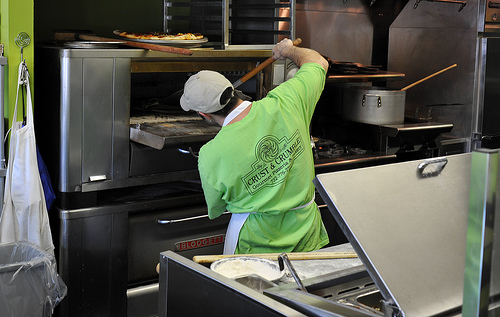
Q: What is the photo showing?
A: It is showing a kitchen.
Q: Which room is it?
A: It is a kitchen.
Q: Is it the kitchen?
A: Yes, it is the kitchen.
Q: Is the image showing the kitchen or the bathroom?
A: It is showing the kitchen.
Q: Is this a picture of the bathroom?
A: No, the picture is showing the kitchen.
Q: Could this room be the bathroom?
A: No, it is the kitchen.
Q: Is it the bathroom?
A: No, it is the kitchen.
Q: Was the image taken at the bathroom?
A: No, the picture was taken in the kitchen.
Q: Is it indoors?
A: Yes, it is indoors.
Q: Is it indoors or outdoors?
A: It is indoors.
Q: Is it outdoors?
A: No, it is indoors.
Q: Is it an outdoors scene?
A: No, it is indoors.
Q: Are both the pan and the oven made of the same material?
A: Yes, both the pan and the oven are made of metal.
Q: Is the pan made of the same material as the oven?
A: Yes, both the pan and the oven are made of metal.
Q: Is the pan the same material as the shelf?
A: Yes, both the pan and the shelf are made of metal.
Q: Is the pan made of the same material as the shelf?
A: Yes, both the pan and the shelf are made of metal.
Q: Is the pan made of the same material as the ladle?
A: Yes, both the pan and the ladle are made of metal.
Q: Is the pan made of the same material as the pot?
A: Yes, both the pan and the pot are made of metal.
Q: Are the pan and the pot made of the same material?
A: Yes, both the pan and the pot are made of metal.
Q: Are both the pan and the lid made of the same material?
A: Yes, both the pan and the lid are made of metal.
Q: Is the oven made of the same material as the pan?
A: Yes, both the oven and the pan are made of metal.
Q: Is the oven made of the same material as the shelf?
A: Yes, both the oven and the shelf are made of metal.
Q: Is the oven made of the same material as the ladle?
A: Yes, both the oven and the ladle are made of metal.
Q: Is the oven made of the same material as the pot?
A: Yes, both the oven and the pot are made of metal.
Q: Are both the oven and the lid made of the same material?
A: Yes, both the oven and the lid are made of metal.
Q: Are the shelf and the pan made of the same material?
A: Yes, both the shelf and the pan are made of metal.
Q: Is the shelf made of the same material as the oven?
A: Yes, both the shelf and the oven are made of metal.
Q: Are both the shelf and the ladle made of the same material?
A: Yes, both the shelf and the ladle are made of metal.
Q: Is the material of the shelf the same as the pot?
A: Yes, both the shelf and the pot are made of metal.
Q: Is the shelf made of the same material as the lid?
A: Yes, both the shelf and the lid are made of metal.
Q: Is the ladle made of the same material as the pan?
A: Yes, both the ladle and the pan are made of metal.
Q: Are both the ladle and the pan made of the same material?
A: Yes, both the ladle and the pan are made of metal.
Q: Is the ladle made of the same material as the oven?
A: Yes, both the ladle and the oven are made of metal.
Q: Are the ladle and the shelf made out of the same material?
A: Yes, both the ladle and the shelf are made of metal.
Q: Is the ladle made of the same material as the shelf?
A: Yes, both the ladle and the shelf are made of metal.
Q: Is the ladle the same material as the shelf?
A: Yes, both the ladle and the shelf are made of metal.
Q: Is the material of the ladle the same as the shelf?
A: Yes, both the ladle and the shelf are made of metal.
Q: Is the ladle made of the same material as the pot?
A: Yes, both the ladle and the pot are made of metal.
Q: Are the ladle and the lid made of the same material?
A: Yes, both the ladle and the lid are made of metal.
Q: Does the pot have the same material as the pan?
A: Yes, both the pot and the pan are made of metal.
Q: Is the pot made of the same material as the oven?
A: Yes, both the pot and the oven are made of metal.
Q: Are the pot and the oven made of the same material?
A: Yes, both the pot and the oven are made of metal.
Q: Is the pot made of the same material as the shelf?
A: Yes, both the pot and the shelf are made of metal.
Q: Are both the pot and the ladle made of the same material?
A: Yes, both the pot and the ladle are made of metal.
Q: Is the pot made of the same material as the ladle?
A: Yes, both the pot and the ladle are made of metal.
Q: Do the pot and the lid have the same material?
A: Yes, both the pot and the lid are made of metal.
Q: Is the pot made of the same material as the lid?
A: Yes, both the pot and the lid are made of metal.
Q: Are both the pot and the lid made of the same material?
A: Yes, both the pot and the lid are made of metal.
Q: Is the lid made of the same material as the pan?
A: Yes, both the lid and the pan are made of metal.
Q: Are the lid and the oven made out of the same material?
A: Yes, both the lid and the oven are made of metal.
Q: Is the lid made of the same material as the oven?
A: Yes, both the lid and the oven are made of metal.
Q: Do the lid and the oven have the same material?
A: Yes, both the lid and the oven are made of metal.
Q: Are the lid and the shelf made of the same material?
A: Yes, both the lid and the shelf are made of metal.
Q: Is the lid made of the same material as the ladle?
A: Yes, both the lid and the ladle are made of metal.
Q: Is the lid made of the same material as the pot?
A: Yes, both the lid and the pot are made of metal.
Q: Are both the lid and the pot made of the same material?
A: Yes, both the lid and the pot are made of metal.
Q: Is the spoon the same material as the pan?
A: No, the spoon is made of wood and the pan is made of metal.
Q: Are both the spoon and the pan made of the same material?
A: No, the spoon is made of wood and the pan is made of metal.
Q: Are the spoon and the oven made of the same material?
A: No, the spoon is made of wood and the oven is made of metal.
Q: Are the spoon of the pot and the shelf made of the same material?
A: No, the spoon is made of wood and the shelf is made of metal.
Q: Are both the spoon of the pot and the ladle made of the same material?
A: No, the spoon is made of wood and the ladle is made of metal.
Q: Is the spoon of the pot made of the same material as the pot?
A: No, the spoon is made of wood and the pot is made of metal.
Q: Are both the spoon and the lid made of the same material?
A: No, the spoon is made of wood and the lid is made of metal.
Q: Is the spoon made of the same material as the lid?
A: No, the spoon is made of wood and the lid is made of metal.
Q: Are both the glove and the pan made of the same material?
A: No, the glove is made of plastic and the pan is made of metal.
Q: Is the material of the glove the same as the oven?
A: No, the glove is made of plastic and the oven is made of metal.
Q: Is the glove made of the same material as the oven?
A: No, the glove is made of plastic and the oven is made of metal.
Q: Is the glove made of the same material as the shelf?
A: No, the glove is made of plastic and the shelf is made of metal.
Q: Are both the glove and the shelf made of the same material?
A: No, the glove is made of plastic and the shelf is made of metal.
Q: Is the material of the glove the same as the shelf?
A: No, the glove is made of plastic and the shelf is made of metal.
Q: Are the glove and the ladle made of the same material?
A: No, the glove is made of plastic and the ladle is made of metal.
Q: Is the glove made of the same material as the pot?
A: No, the glove is made of plastic and the pot is made of metal.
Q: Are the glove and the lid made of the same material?
A: No, the glove is made of plastic and the lid is made of metal.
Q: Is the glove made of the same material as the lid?
A: No, the glove is made of plastic and the lid is made of metal.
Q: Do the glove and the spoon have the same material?
A: No, the glove is made of plastic and the spoon is made of wood.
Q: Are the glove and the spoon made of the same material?
A: No, the glove is made of plastic and the spoon is made of wood.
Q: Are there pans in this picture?
A: Yes, there is a pan.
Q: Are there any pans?
A: Yes, there is a pan.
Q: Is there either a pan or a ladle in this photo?
A: Yes, there is a pan.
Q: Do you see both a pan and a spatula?
A: No, there is a pan but no spatulas.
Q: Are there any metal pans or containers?
A: Yes, there is a metal pan.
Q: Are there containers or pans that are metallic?
A: Yes, the pan is metallic.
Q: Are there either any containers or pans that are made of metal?
A: Yes, the pan is made of metal.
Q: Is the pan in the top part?
A: Yes, the pan is in the top of the image.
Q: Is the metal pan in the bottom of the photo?
A: No, the pan is in the top of the image.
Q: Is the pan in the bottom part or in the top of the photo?
A: The pan is in the top of the image.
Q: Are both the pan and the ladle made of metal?
A: Yes, both the pan and the ladle are made of metal.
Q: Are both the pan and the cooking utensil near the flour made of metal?
A: Yes, both the pan and the ladle are made of metal.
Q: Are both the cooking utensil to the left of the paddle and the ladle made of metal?
A: Yes, both the pan and the ladle are made of metal.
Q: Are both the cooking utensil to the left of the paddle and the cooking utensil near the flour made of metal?
A: Yes, both the pan and the ladle are made of metal.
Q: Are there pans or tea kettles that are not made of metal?
A: No, there is a pan but it is made of metal.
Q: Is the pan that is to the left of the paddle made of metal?
A: Yes, the pan is made of metal.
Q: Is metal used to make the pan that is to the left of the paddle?
A: Yes, the pan is made of metal.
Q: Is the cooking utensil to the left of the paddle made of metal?
A: Yes, the pan is made of metal.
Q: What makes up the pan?
A: The pan is made of metal.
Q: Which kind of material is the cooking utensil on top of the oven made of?
A: The pan is made of metal.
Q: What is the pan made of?
A: The pan is made of metal.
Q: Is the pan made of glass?
A: No, the pan is made of metal.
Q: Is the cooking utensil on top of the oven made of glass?
A: No, the pan is made of metal.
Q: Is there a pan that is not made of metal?
A: No, there is a pan but it is made of metal.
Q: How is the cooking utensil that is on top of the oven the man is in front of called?
A: The cooking utensil is a pan.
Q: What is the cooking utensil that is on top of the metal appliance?
A: The cooking utensil is a pan.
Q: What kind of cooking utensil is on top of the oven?
A: The cooking utensil is a pan.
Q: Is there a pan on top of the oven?
A: Yes, there is a pan on top of the oven.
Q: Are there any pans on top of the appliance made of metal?
A: Yes, there is a pan on top of the oven.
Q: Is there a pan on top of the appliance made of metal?
A: Yes, there is a pan on top of the oven.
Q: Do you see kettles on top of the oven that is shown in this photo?
A: No, there is a pan on top of the oven.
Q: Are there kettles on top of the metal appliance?
A: No, there is a pan on top of the oven.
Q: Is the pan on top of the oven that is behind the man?
A: Yes, the pan is on top of the oven.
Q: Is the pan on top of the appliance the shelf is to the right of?
A: Yes, the pan is on top of the oven.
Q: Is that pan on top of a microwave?
A: No, the pan is on top of the oven.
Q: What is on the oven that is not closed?
A: The pan is on the oven.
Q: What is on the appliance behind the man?
A: The pan is on the oven.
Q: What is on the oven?
A: The pan is on the oven.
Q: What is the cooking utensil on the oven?
A: The cooking utensil is a pan.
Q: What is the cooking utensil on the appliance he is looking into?
A: The cooking utensil is a pan.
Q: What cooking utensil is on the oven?
A: The cooking utensil is a pan.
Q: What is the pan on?
A: The pan is on the oven.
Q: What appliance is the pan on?
A: The pan is on the oven.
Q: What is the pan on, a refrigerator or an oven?
A: The pan is on an oven.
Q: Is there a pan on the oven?
A: Yes, there is a pan on the oven.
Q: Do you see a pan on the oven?
A: Yes, there is a pan on the oven.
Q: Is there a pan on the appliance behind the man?
A: Yes, there is a pan on the oven.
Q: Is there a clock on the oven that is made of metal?
A: No, there is a pan on the oven.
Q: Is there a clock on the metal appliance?
A: No, there is a pan on the oven.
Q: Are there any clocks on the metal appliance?
A: No, there is a pan on the oven.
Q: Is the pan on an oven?
A: Yes, the pan is on an oven.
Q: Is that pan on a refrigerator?
A: No, the pan is on an oven.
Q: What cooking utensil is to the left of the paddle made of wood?
A: The cooking utensil is a pan.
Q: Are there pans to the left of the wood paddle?
A: Yes, there is a pan to the left of the oar.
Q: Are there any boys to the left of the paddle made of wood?
A: No, there is a pan to the left of the oar.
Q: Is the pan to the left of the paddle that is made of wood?
A: Yes, the pan is to the left of the oar.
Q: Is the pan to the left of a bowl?
A: No, the pan is to the left of the oar.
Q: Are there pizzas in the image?
A: Yes, there is a pizza.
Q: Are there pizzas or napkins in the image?
A: Yes, there is a pizza.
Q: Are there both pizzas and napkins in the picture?
A: No, there is a pizza but no napkins.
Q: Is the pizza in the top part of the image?
A: Yes, the pizza is in the top of the image.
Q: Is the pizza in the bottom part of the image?
A: No, the pizza is in the top of the image.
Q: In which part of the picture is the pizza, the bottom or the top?
A: The pizza is in the top of the image.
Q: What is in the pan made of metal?
A: The pizza is in the pan.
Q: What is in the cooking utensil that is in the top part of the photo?
A: The pizza is in the pan.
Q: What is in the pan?
A: The pizza is in the pan.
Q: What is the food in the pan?
A: The food is a pizza.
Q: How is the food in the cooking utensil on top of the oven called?
A: The food is a pizza.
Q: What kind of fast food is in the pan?
A: The food is a pizza.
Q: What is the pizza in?
A: The pizza is in the pan.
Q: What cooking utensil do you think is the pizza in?
A: The pizza is in the pan.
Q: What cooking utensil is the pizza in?
A: The pizza is in the pan.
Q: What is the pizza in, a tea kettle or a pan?
A: The pizza is in a pan.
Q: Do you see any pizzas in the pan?
A: Yes, there is a pizza in the pan.